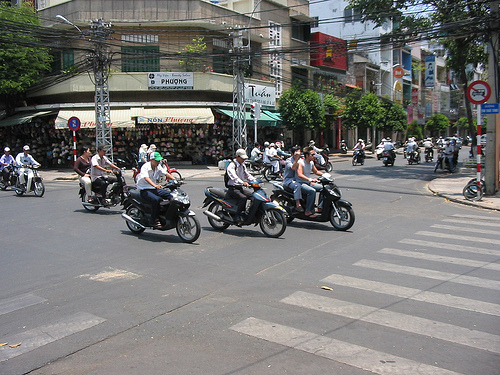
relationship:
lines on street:
[1, 210, 499, 374] [0, 143, 499, 374]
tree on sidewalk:
[344, 0, 500, 174] [429, 150, 500, 209]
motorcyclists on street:
[0, 135, 489, 243] [0, 143, 499, 374]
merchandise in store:
[2, 109, 287, 168] [2, 93, 291, 165]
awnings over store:
[0, 105, 298, 132] [2, 93, 291, 165]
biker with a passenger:
[91, 145, 123, 204] [76, 145, 94, 209]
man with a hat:
[138, 152, 179, 230] [150, 151, 164, 162]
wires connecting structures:
[0, 0, 499, 109] [89, 15, 251, 165]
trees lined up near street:
[285, 80, 486, 150] [0, 143, 499, 374]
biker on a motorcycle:
[91, 145, 123, 204] [78, 169, 136, 215]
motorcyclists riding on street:
[0, 135, 489, 243] [0, 143, 499, 374]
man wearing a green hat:
[138, 152, 179, 230] [150, 151, 164, 162]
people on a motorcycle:
[284, 146, 328, 219] [270, 179, 357, 231]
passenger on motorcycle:
[76, 145, 94, 209] [78, 169, 136, 215]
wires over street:
[0, 0, 499, 109] [0, 143, 499, 374]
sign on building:
[147, 72, 195, 94] [0, 1, 310, 170]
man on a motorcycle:
[138, 152, 179, 230] [123, 184, 202, 245]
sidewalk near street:
[429, 150, 500, 209] [0, 143, 499, 374]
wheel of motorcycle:
[125, 206, 148, 233] [123, 184, 202, 245]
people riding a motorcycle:
[284, 146, 328, 219] [270, 179, 357, 231]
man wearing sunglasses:
[300, 147, 328, 219] [311, 151, 317, 156]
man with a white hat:
[138, 152, 179, 230] [150, 151, 164, 162]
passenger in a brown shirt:
[76, 145, 94, 209] [75, 157, 92, 175]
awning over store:
[138, 106, 214, 124] [2, 93, 291, 165]